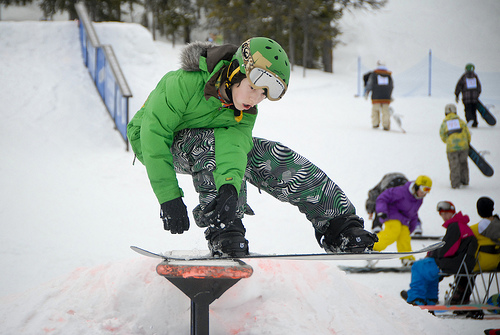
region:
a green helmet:
[226, 33, 293, 100]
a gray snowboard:
[132, 236, 448, 261]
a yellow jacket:
[440, 115, 471, 151]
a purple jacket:
[378, 176, 420, 231]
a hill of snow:
[0, 2, 163, 152]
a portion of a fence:
[428, 55, 497, 100]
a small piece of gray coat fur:
[180, 35, 210, 70]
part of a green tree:
[146, 0, 197, 45]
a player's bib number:
[378, 71, 390, 86]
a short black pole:
[191, 291, 213, 333]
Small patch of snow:
[68, 212, 88, 235]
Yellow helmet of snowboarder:
[414, 174, 434, 186]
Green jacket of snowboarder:
[159, 83, 201, 125]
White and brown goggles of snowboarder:
[253, 62, 288, 89]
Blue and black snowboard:
[468, 147, 491, 177]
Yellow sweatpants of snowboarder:
[385, 220, 417, 254]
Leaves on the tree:
[316, 17, 328, 34]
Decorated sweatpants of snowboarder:
[247, 145, 339, 212]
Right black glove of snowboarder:
[160, 200, 185, 227]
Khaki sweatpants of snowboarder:
[372, 108, 388, 130]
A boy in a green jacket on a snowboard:
[110, 22, 454, 284]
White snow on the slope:
[24, 108, 106, 251]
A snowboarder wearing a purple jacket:
[363, 163, 435, 282]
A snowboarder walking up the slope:
[360, 54, 414, 143]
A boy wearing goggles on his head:
[393, 196, 486, 324]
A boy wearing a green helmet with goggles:
[192, 35, 298, 126]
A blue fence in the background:
[68, 3, 137, 140]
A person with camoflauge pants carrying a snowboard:
[431, 96, 498, 196]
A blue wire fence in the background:
[393, 47, 453, 98]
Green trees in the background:
[276, 0, 340, 35]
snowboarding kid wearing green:
[136, 33, 377, 250]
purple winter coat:
[376, 179, 421, 229]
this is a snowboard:
[120, 237, 450, 277]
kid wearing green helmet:
[231, 30, 295, 98]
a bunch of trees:
[113, 1, 339, 55]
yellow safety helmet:
[410, 170, 437, 196]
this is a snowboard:
[462, 138, 497, 189]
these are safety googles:
[246, 63, 289, 105]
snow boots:
[194, 188, 380, 264]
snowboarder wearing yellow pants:
[341, 216, 428, 278]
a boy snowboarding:
[119, 40, 453, 264]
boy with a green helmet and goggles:
[224, 37, 291, 113]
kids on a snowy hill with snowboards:
[346, 57, 499, 334]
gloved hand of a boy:
[155, 195, 192, 235]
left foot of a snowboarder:
[319, 209, 379, 257]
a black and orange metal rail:
[154, 257, 253, 334]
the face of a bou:
[231, 76, 270, 113]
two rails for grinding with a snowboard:
[69, 3, 134, 155]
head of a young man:
[436, 200, 458, 222]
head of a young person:
[411, 176, 431, 198]